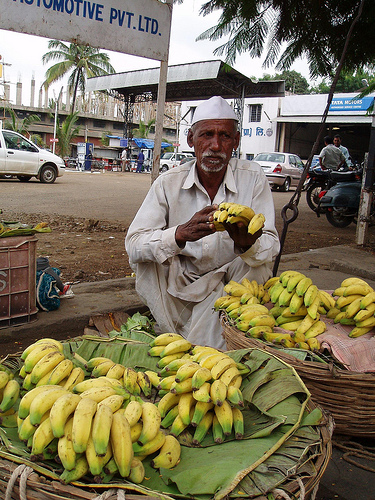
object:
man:
[124, 94, 280, 352]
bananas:
[247, 213, 266, 235]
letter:
[151, 18, 159, 34]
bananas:
[232, 205, 255, 220]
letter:
[126, 11, 134, 29]